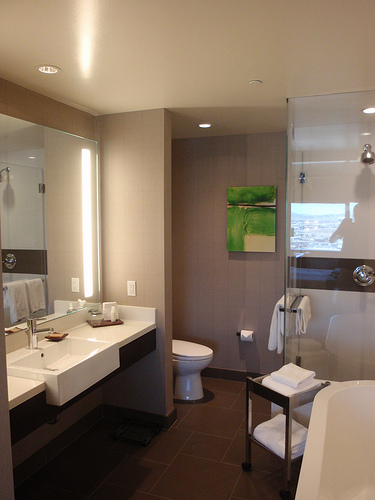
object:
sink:
[7, 333, 120, 405]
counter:
[0, 311, 156, 401]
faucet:
[25, 317, 54, 350]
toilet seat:
[170, 335, 213, 360]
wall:
[171, 132, 374, 381]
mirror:
[0, 114, 100, 338]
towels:
[5, 279, 29, 325]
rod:
[2, 279, 45, 290]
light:
[197, 122, 212, 128]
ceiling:
[1, 1, 373, 139]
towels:
[270, 362, 316, 389]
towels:
[254, 413, 310, 460]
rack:
[241, 362, 329, 500]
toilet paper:
[240, 329, 254, 342]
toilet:
[171, 338, 213, 399]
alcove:
[165, 110, 374, 424]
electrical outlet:
[71, 277, 79, 292]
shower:
[1, 163, 47, 328]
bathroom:
[0, 0, 374, 497]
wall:
[0, 77, 105, 469]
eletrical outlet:
[127, 280, 137, 296]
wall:
[96, 113, 171, 422]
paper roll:
[240, 329, 254, 342]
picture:
[227, 182, 277, 254]